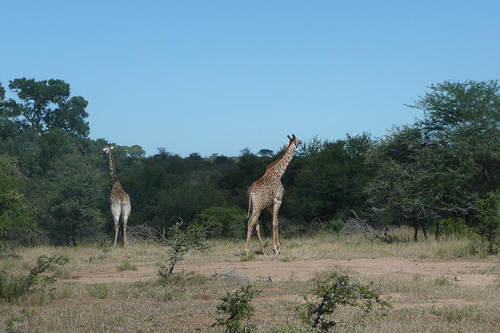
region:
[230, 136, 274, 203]
A giraffe is visible.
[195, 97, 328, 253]
A giraffe is visible.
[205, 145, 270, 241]
A giraffe is visible.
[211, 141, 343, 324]
A giraffe is visible.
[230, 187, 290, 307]
A giraffe is visible.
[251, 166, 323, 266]
A giraffe is visible.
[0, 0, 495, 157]
the sky is blue.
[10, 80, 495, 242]
the trees are green.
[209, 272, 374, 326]
weeds growing in the grass.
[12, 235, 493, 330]
the ground is brown.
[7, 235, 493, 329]
the grass is patchy.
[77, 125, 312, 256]
two giraffes are roaming.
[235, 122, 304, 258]
the giraffe is brown and tan.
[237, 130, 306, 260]
the giraffe has four legs.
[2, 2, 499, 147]
the sky is clear.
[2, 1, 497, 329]
it is day time.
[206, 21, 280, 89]
the sky is blue.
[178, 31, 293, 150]
the sky is blue.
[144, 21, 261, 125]
the sky is blue.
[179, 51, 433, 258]
the sky is blue.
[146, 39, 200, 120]
the sky is blue.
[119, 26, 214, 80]
the sky is blue.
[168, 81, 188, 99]
the sky is blue.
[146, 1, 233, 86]
the sky is blue.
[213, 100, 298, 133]
the sky is blue.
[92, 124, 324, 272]
Two giraffes looking for food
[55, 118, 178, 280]
A giraffe standing in a field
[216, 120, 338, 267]
A giraffe looking for food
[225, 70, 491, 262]
A giraffe walking into the woods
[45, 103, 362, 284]
Two giraffes walking into the woods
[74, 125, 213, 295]
A small tree and a giraffe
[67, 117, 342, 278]
A small tree and two giraffes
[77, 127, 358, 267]
Two giraffes in a field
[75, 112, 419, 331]
A open field with two giraffes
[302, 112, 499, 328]
A small tree in a field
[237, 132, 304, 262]
adult giraffe facing right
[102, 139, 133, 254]
adult giraffe facing away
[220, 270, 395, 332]
two bushes growing in desert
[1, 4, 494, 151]
bright blue clearless sky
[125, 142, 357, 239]
tree-covered hill rising in distance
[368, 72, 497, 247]
cluster of low trees on right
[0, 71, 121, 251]
large green trees on left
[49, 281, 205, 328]
dead/ dying grass on the ground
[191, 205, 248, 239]
large shrub dead center of photo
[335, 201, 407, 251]
large dead tree branch